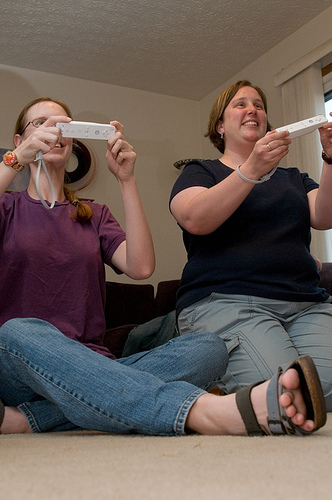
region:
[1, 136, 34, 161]
watch on ladies hand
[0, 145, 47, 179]
watch on ladies hand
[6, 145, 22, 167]
watch on ladies hand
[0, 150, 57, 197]
watch on ladies hand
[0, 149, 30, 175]
watch on ladies hand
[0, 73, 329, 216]
two women holding game controllers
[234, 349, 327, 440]
woman wearing a sandal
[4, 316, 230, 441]
woman sitting cross-legged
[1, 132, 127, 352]
woman wearing a purple shirt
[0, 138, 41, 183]
woman wearing a wrist watch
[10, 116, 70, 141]
woman wearing glasses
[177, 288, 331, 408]
woman wearing grey pants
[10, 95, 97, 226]
woman wearing her hair in a braid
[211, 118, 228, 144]
woman wearing a small earring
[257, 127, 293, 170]
woman wearing a ring on her middle finger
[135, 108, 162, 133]
this is the wall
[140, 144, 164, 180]
the wall is white in color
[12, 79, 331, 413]
these are two women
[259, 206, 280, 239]
the t-shirt is black in color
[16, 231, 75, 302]
the t-shirt is purple in color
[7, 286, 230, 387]
the woman is seated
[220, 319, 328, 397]
the woman is kneeling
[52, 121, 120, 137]
the woman is holding an object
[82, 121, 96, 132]
the object is white in color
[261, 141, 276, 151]
this is a ring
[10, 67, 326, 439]
two women sitting on floor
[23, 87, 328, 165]
two women holding wii remotes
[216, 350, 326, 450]
woman wearing leather sandal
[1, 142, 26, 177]
orange and yellow watch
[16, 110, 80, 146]
woman wearing eyeglasses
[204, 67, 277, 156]
woman with short brown hair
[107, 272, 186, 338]
brown sofa behind women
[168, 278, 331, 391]
woman wearing grey cargo pants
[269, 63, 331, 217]
white blinds on window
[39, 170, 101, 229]
woman with braided hair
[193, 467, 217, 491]
the floor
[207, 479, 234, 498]
the floor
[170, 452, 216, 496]
the floor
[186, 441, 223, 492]
the floor